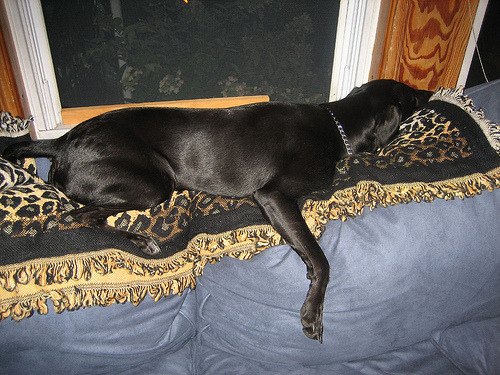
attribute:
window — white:
[4, 2, 379, 145]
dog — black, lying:
[5, 79, 434, 342]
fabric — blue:
[2, 77, 499, 374]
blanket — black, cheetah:
[1, 87, 498, 320]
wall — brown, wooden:
[380, 2, 480, 91]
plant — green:
[49, 3, 328, 108]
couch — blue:
[1, 74, 498, 374]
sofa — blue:
[1, 76, 499, 374]